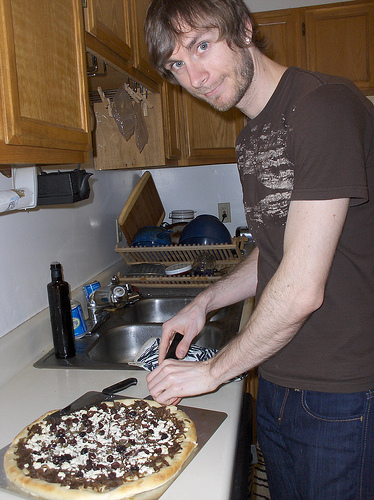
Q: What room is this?
A: It is a kitchen.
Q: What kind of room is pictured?
A: It is a kitchen.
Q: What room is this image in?
A: It is at the kitchen.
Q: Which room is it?
A: It is a kitchen.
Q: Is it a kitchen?
A: Yes, it is a kitchen.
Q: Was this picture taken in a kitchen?
A: Yes, it was taken in a kitchen.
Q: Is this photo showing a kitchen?
A: Yes, it is showing a kitchen.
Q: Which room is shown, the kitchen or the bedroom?
A: It is the kitchen.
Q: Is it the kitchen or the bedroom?
A: It is the kitchen.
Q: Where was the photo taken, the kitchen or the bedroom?
A: It was taken at the kitchen.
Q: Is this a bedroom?
A: No, it is a kitchen.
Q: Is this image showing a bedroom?
A: No, the picture is showing a kitchen.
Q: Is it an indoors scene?
A: Yes, it is indoors.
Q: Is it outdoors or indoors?
A: It is indoors.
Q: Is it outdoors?
A: No, it is indoors.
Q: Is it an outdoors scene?
A: No, it is indoors.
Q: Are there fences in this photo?
A: No, there are no fences.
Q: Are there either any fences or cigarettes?
A: No, there are no fences or cigarettes.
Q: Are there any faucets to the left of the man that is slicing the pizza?
A: Yes, there is a faucet to the left of the man.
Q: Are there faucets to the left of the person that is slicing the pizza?
A: Yes, there is a faucet to the left of the man.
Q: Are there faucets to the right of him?
A: No, the faucet is to the left of the man.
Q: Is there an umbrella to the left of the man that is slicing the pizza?
A: No, there is a faucet to the left of the man.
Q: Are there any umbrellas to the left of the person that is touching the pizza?
A: No, there is a faucet to the left of the man.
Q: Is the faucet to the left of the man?
A: Yes, the faucet is to the left of the man.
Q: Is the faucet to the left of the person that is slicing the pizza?
A: Yes, the faucet is to the left of the man.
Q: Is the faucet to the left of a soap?
A: No, the faucet is to the left of the man.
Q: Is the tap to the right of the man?
A: No, the tap is to the left of the man.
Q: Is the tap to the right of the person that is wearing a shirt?
A: No, the tap is to the left of the man.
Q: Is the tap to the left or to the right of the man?
A: The tap is to the left of the man.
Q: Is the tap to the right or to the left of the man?
A: The tap is to the left of the man.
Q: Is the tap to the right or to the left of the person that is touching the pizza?
A: The tap is to the left of the man.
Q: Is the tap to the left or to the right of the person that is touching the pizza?
A: The tap is to the left of the man.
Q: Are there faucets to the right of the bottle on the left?
A: Yes, there is a faucet to the right of the bottle.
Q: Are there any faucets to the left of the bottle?
A: No, the faucet is to the right of the bottle.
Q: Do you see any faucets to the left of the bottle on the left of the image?
A: No, the faucet is to the right of the bottle.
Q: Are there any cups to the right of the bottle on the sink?
A: No, there is a faucet to the right of the bottle.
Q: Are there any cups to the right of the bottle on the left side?
A: No, there is a faucet to the right of the bottle.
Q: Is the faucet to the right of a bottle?
A: Yes, the faucet is to the right of a bottle.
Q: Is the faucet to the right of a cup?
A: No, the faucet is to the right of a bottle.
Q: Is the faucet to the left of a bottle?
A: No, the faucet is to the right of a bottle.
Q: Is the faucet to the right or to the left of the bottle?
A: The faucet is to the right of the bottle.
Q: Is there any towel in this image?
A: Yes, there is a towel.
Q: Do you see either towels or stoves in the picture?
A: Yes, there is a towel.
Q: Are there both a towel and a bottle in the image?
A: Yes, there are both a towel and a bottle.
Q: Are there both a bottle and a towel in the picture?
A: Yes, there are both a towel and a bottle.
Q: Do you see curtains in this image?
A: No, there are no curtains.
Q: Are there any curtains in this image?
A: No, there are no curtains.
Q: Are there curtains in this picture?
A: No, there are no curtains.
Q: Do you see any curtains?
A: No, there are no curtains.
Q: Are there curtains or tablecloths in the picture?
A: No, there are no curtains or tablecloths.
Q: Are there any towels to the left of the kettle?
A: Yes, there is a towel to the left of the kettle.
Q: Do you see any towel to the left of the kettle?
A: Yes, there is a towel to the left of the kettle.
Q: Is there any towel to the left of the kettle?
A: Yes, there is a towel to the left of the kettle.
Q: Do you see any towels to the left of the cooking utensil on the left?
A: Yes, there is a towel to the left of the kettle.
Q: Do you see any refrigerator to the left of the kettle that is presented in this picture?
A: No, there is a towel to the left of the kettle.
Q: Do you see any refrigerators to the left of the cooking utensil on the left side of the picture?
A: No, there is a towel to the left of the kettle.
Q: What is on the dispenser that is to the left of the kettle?
A: The towel is on the dispenser.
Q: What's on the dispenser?
A: The towel is on the dispenser.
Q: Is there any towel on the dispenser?
A: Yes, there is a towel on the dispenser.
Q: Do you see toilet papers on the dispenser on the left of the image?
A: No, there is a towel on the dispenser.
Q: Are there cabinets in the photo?
A: Yes, there is a cabinet.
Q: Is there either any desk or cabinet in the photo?
A: Yes, there is a cabinet.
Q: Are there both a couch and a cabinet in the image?
A: No, there is a cabinet but no couches.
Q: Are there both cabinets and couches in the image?
A: No, there is a cabinet but no couches.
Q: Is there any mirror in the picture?
A: No, there are no mirrors.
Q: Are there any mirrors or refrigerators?
A: No, there are no mirrors or refrigerators.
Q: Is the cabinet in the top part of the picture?
A: Yes, the cabinet is in the top of the image.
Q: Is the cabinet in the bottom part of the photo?
A: No, the cabinet is in the top of the image.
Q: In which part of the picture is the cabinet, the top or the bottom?
A: The cabinet is in the top of the image.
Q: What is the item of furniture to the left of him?
A: The piece of furniture is a cabinet.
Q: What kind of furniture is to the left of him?
A: The piece of furniture is a cabinet.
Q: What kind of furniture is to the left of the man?
A: The piece of furniture is a cabinet.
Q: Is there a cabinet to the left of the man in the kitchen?
A: Yes, there is a cabinet to the left of the man.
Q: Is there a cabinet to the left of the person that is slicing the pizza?
A: Yes, there is a cabinet to the left of the man.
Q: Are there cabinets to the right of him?
A: No, the cabinet is to the left of the man.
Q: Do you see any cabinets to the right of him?
A: No, the cabinet is to the left of the man.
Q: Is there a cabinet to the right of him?
A: No, the cabinet is to the left of the man.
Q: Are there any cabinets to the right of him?
A: No, the cabinet is to the left of the man.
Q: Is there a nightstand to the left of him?
A: No, there is a cabinet to the left of the man.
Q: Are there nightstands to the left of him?
A: No, there is a cabinet to the left of the man.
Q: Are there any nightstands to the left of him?
A: No, there is a cabinet to the left of the man.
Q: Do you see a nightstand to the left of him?
A: No, there is a cabinet to the left of the man.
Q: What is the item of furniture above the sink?
A: The piece of furniture is a cabinet.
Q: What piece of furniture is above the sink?
A: The piece of furniture is a cabinet.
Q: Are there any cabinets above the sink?
A: Yes, there is a cabinet above the sink.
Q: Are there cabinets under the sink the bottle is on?
A: No, the cabinet is above the sink.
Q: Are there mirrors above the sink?
A: No, there is a cabinet above the sink.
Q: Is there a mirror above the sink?
A: No, there is a cabinet above the sink.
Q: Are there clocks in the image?
A: No, there are no clocks.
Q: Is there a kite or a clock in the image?
A: No, there are no clocks or kites.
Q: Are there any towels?
A: Yes, there is a towel.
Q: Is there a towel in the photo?
A: Yes, there is a towel.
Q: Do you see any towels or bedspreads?
A: Yes, there is a towel.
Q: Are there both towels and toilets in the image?
A: No, there is a towel but no toilets.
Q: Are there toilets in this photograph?
A: No, there are no toilets.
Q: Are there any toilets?
A: No, there are no toilets.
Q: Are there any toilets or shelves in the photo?
A: No, there are no toilets or shelves.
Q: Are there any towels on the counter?
A: Yes, there is a towel on the counter.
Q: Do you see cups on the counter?
A: No, there is a towel on the counter.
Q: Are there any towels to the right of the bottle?
A: Yes, there is a towel to the right of the bottle.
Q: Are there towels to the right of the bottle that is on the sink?
A: Yes, there is a towel to the right of the bottle.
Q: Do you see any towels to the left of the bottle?
A: No, the towel is to the right of the bottle.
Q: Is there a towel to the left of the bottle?
A: No, the towel is to the right of the bottle.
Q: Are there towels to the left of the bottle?
A: No, the towel is to the right of the bottle.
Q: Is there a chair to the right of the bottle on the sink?
A: No, there is a towel to the right of the bottle.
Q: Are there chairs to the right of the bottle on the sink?
A: No, there is a towel to the right of the bottle.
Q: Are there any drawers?
A: No, there are no drawers.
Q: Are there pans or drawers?
A: No, there are no drawers or pans.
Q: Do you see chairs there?
A: No, there are no chairs.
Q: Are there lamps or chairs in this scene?
A: No, there are no chairs or lamps.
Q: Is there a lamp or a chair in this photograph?
A: No, there are no chairs or lamps.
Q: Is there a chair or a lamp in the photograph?
A: No, there are no chairs or lamps.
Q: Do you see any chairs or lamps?
A: No, there are no chairs or lamps.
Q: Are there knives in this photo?
A: Yes, there is a knife.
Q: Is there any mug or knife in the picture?
A: Yes, there is a knife.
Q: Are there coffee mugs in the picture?
A: No, there are no coffee mugs.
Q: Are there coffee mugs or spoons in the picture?
A: No, there are no coffee mugs or spoons.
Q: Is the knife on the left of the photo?
A: Yes, the knife is on the left of the image.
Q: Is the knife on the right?
A: No, the knife is on the left of the image.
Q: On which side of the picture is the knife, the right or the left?
A: The knife is on the left of the image.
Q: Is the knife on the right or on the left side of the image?
A: The knife is on the left of the image.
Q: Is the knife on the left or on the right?
A: The knife is on the left of the image.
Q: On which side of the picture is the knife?
A: The knife is on the left of the image.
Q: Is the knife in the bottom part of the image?
A: Yes, the knife is in the bottom of the image.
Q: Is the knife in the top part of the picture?
A: No, the knife is in the bottom of the image.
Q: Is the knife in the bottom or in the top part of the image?
A: The knife is in the bottom of the image.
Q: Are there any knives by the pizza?
A: Yes, there is a knife by the pizza.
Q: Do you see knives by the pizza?
A: Yes, there is a knife by the pizza.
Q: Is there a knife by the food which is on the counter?
A: Yes, there is a knife by the pizza.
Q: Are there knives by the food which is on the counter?
A: Yes, there is a knife by the pizza.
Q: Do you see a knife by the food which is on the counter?
A: Yes, there is a knife by the pizza.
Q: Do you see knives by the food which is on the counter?
A: Yes, there is a knife by the pizza.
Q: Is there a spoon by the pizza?
A: No, there is a knife by the pizza.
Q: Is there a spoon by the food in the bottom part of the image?
A: No, there is a knife by the pizza.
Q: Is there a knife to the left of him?
A: Yes, there is a knife to the left of the man.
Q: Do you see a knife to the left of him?
A: Yes, there is a knife to the left of the man.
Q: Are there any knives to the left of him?
A: Yes, there is a knife to the left of the man.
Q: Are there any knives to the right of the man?
A: No, the knife is to the left of the man.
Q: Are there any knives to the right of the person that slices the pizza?
A: No, the knife is to the left of the man.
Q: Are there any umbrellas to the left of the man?
A: No, there is a knife to the left of the man.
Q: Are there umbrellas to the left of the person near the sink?
A: No, there is a knife to the left of the man.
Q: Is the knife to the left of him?
A: Yes, the knife is to the left of a man.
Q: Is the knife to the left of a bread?
A: No, the knife is to the left of a man.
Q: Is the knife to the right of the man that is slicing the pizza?
A: No, the knife is to the left of the man.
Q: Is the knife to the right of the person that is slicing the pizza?
A: No, the knife is to the left of the man.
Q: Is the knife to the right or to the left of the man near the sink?
A: The knife is to the left of the man.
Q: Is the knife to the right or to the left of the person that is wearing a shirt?
A: The knife is to the left of the man.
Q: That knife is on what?
A: The knife is on the tray.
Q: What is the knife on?
A: The knife is on the tray.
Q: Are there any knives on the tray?
A: Yes, there is a knife on the tray.